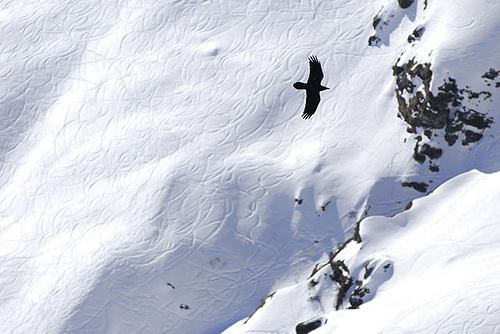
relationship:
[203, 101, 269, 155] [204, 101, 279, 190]
lines are in snow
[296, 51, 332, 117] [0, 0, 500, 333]
bird in landscape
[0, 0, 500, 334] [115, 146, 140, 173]
snow has a swirl pattern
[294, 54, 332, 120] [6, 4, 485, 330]
bird flying over mountain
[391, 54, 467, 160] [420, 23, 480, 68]
rock portions poking out of snow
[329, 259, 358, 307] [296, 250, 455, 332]
rocks peeking through snow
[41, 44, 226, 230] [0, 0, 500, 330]
snow covering mountain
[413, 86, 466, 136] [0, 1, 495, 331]
spot of moutain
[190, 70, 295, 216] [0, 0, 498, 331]
snow tracks in snow